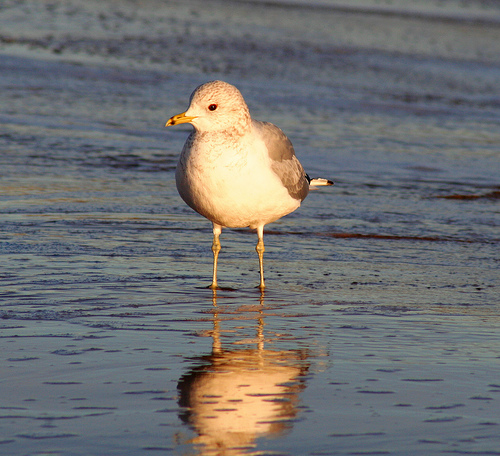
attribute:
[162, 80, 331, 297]
bird — white, gray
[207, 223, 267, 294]
legs — yellowish